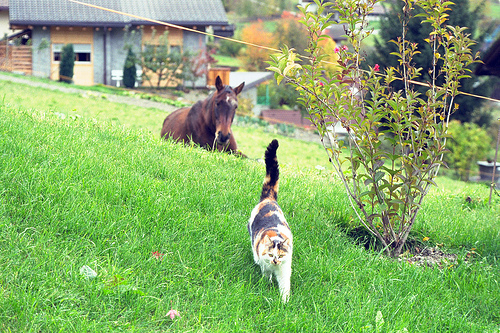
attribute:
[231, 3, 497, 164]
blurry trees — tall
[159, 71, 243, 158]
horse — brown and white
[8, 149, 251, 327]
grass — green , long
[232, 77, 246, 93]
ear — brown 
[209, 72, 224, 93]
ear — brown 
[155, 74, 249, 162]
horse — laying down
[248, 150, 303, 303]
cat — orange black and white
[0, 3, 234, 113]
building — Small 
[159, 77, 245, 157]
horse — brown/black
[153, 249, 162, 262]
flower — Small , red 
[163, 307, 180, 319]
flower — Small , red 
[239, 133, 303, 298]
cat — walking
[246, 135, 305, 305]
cat — tabby , Small 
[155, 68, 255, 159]
horse — brown 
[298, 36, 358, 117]
leaves — many colors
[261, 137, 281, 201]
tail — black and orange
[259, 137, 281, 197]
tail — black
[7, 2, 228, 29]
roof — metal 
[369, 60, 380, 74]
flower — pink 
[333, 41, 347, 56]
flower — pink 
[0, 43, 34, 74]
fence — brown , wooden 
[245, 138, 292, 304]
cat — calico 